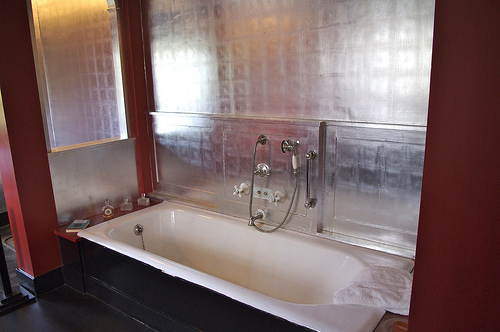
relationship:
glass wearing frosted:
[163, 51, 242, 156] [215, 122, 237, 143]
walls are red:
[12, 62, 73, 320] [12, 251, 36, 295]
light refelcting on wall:
[123, 50, 200, 182] [166, 100, 198, 129]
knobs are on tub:
[222, 124, 338, 207] [138, 212, 354, 332]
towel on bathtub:
[331, 260, 412, 310] [66, 199, 414, 332]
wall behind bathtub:
[147, 2, 434, 250] [77, 199, 408, 329]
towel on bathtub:
[331, 264, 413, 316] [77, 199, 408, 329]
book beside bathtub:
[64, 216, 89, 232] [77, 199, 408, 329]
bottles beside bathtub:
[99, 194, 155, 217] [77, 199, 408, 329]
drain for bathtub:
[131, 222, 148, 251] [77, 199, 408, 329]